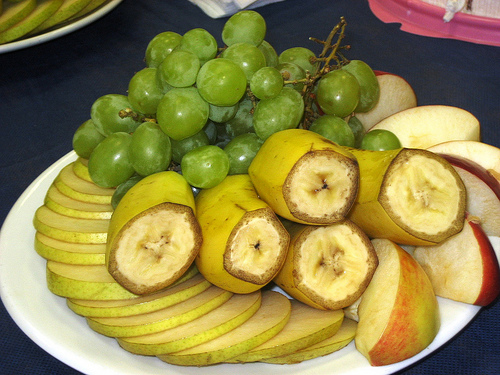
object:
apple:
[395, 211, 499, 309]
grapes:
[154, 84, 212, 142]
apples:
[52, 160, 119, 206]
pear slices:
[154, 288, 293, 367]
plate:
[0, 146, 497, 375]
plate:
[1, 0, 128, 53]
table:
[1, 0, 500, 374]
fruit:
[0, 0, 106, 47]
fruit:
[34, 8, 500, 369]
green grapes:
[89, 92, 146, 139]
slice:
[341, 236, 442, 368]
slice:
[421, 138, 500, 182]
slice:
[364, 103, 483, 152]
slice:
[342, 68, 419, 134]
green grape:
[313, 68, 362, 119]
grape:
[312, 67, 363, 119]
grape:
[335, 57, 383, 117]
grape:
[307, 113, 357, 149]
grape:
[194, 56, 249, 108]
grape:
[222, 132, 266, 176]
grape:
[178, 144, 233, 191]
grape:
[126, 120, 173, 178]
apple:
[435, 151, 499, 237]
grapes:
[220, 8, 268, 50]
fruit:
[44, 181, 116, 221]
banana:
[104, 169, 205, 297]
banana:
[248, 128, 362, 227]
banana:
[338, 144, 469, 249]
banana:
[193, 172, 293, 295]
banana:
[275, 216, 379, 312]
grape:
[85, 130, 138, 188]